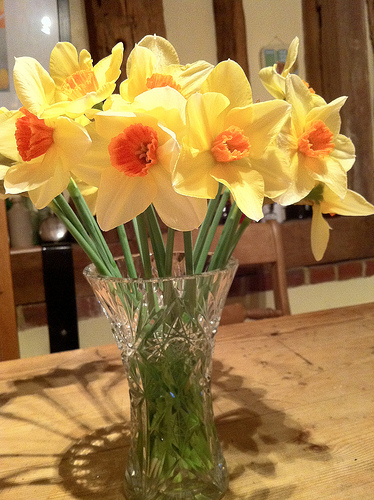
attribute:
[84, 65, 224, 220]
flower — yellow, green, orange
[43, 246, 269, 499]
vase — clear, glass, see through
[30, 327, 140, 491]
shadow — cast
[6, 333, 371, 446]
table — wooden, brown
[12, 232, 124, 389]
chair — wooden, here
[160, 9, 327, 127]
wall — here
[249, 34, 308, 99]
art — hanging, hung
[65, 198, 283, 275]
stem — green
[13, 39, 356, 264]
boquet — yellow, here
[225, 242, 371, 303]
brick — red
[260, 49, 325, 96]
picture — hanging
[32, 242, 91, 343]
belt — black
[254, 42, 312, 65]
frame — silver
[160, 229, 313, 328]
object — here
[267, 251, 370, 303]
trim — brick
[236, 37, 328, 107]
plaque — hanging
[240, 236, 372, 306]
wall — brick